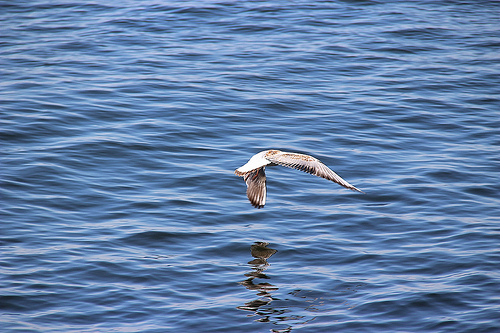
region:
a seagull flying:
[193, 108, 400, 220]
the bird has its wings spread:
[207, 123, 445, 259]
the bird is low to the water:
[186, 111, 379, 218]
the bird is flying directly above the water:
[196, 90, 387, 232]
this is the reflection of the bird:
[232, 227, 319, 332]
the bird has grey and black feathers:
[267, 145, 374, 207]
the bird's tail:
[219, 152, 265, 181]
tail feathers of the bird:
[222, 156, 259, 177]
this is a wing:
[267, 148, 387, 200]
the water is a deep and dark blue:
[40, 40, 461, 286]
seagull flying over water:
[211, 128, 356, 224]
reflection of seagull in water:
[241, 231, 281, 280]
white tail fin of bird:
[250, 154, 265, 169]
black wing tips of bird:
[281, 163, 326, 183]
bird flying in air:
[230, 142, 358, 229]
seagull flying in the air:
[226, 116, 349, 209]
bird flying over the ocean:
[201, 113, 368, 241]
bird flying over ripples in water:
[247, 137, 347, 208]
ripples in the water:
[0, 47, 128, 247]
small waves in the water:
[31, 30, 220, 292]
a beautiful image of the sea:
[14, 17, 469, 318]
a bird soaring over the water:
[181, 123, 398, 275]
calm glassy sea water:
[36, 89, 106, 203]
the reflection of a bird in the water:
[202, 241, 334, 306]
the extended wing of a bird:
[278, 145, 353, 194]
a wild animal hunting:
[221, 147, 345, 218]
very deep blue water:
[24, 22, 204, 164]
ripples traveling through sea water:
[10, 5, 489, 110]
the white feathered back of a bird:
[230, 151, 270, 178]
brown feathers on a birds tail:
[226, 167, 248, 178]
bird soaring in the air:
[248, 133, 363, 196]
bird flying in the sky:
[233, 124, 350, 204]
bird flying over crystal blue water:
[119, 70, 424, 237]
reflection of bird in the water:
[216, 213, 353, 319]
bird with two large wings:
[231, 130, 376, 200]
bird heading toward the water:
[203, 103, 363, 207]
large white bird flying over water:
[225, 126, 365, 226]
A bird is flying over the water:
[11, 22, 489, 317]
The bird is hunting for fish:
[37, 12, 492, 313]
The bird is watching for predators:
[25, 36, 480, 331]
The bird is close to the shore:
[11, 18, 487, 319]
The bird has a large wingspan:
[35, 27, 482, 317]